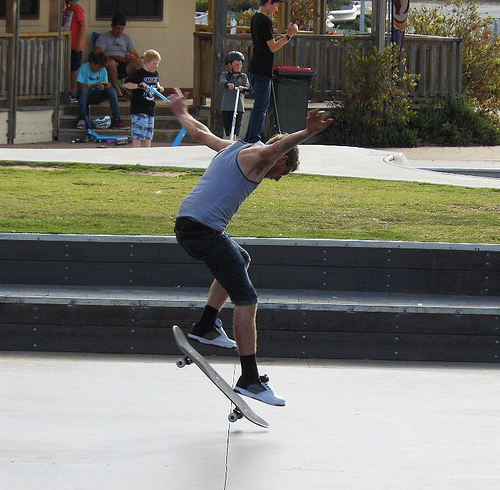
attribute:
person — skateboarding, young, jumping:
[164, 82, 334, 407]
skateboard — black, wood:
[162, 314, 273, 432]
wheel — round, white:
[227, 412, 239, 423]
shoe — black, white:
[235, 370, 294, 412]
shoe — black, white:
[186, 314, 240, 351]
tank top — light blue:
[169, 138, 275, 231]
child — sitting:
[120, 47, 171, 147]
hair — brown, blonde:
[137, 47, 158, 61]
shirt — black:
[124, 70, 166, 117]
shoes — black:
[186, 313, 289, 408]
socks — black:
[235, 349, 266, 376]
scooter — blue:
[220, 85, 248, 138]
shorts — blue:
[127, 110, 157, 141]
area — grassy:
[4, 163, 499, 243]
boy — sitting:
[72, 49, 123, 125]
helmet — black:
[222, 50, 244, 64]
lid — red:
[276, 60, 318, 74]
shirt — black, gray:
[94, 29, 141, 61]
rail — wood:
[208, 31, 460, 107]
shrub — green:
[333, 32, 421, 153]